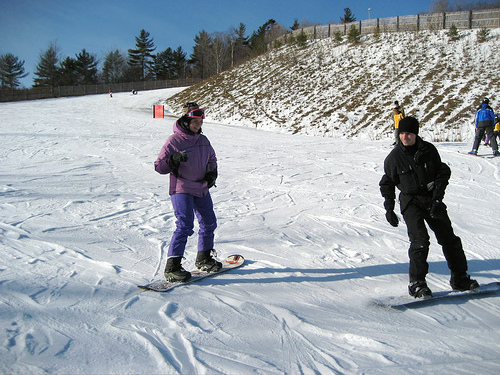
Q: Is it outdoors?
A: Yes, it is outdoors.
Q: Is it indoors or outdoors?
A: It is outdoors.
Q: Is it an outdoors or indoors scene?
A: It is outdoors.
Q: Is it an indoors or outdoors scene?
A: It is outdoors.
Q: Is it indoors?
A: No, it is outdoors.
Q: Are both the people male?
A: No, they are both male and female.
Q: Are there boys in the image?
A: No, there are no boys.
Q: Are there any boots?
A: Yes, there are boots.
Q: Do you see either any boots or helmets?
A: Yes, there are boots.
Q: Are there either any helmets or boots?
A: Yes, there are boots.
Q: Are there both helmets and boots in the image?
A: No, there are boots but no helmets.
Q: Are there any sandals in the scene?
A: No, there are no sandals.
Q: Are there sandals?
A: No, there are no sandals.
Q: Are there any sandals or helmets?
A: No, there are no sandals or helmets.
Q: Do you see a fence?
A: Yes, there is a fence.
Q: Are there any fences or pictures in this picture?
A: Yes, there is a fence.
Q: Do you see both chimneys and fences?
A: No, there is a fence but no chimneys.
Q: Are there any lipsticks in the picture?
A: No, there are no lipsticks.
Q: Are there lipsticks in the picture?
A: No, there are no lipsticks.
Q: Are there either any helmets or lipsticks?
A: No, there are no lipsticks or helmets.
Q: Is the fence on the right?
A: Yes, the fence is on the right of the image.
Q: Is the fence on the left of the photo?
A: No, the fence is on the right of the image.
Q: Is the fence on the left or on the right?
A: The fence is on the right of the image.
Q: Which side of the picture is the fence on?
A: The fence is on the right of the image.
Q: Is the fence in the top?
A: Yes, the fence is in the top of the image.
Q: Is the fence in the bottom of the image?
A: No, the fence is in the top of the image.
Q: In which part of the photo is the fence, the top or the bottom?
A: The fence is in the top of the image.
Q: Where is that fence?
A: The fence is on the hill.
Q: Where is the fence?
A: The fence is on the hill.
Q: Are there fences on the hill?
A: Yes, there is a fence on the hill.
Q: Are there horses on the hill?
A: No, there is a fence on the hill.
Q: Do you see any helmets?
A: No, there are no helmets.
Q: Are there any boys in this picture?
A: No, there are no boys.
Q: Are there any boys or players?
A: No, there are no boys or players.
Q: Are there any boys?
A: No, there are no boys.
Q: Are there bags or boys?
A: No, there are no boys or bags.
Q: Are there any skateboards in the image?
A: No, there are no skateboards.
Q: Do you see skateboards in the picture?
A: No, there are no skateboards.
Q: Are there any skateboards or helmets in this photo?
A: No, there are no skateboards or helmets.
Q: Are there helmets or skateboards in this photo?
A: No, there are no skateboards or helmets.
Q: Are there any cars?
A: No, there are no cars.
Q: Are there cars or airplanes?
A: No, there are no cars or airplanes.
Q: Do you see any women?
A: Yes, there is a woman.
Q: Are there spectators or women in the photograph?
A: Yes, there is a woman.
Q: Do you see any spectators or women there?
A: Yes, there is a woman.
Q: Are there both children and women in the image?
A: No, there is a woman but no children.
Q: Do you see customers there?
A: No, there are no customers.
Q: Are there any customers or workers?
A: No, there are no customers or workers.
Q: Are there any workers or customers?
A: No, there are no customers or workers.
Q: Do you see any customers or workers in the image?
A: No, there are no customers or workers.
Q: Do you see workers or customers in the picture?
A: No, there are no customers or workers.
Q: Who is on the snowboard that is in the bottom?
A: The woman is on the snowboard.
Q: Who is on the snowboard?
A: The woman is on the snowboard.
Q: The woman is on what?
A: The woman is on the snowboard.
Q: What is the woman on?
A: The woman is on the snowboard.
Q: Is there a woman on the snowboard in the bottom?
A: Yes, there is a woman on the snowboard.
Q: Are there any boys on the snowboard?
A: No, there is a woman on the snowboard.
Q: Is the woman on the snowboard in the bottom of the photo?
A: Yes, the woman is on the snow board.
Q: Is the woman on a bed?
A: No, the woman is on the snow board.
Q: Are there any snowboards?
A: Yes, there is a snowboard.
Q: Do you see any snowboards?
A: Yes, there is a snowboard.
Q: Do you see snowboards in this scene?
A: Yes, there is a snowboard.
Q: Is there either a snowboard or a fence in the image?
A: Yes, there is a snowboard.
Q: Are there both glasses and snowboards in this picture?
A: No, there is a snowboard but no glasses.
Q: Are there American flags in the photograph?
A: No, there are no American flags.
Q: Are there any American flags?
A: No, there are no American flags.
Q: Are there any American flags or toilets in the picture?
A: No, there are no American flags or toilets.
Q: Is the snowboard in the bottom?
A: Yes, the snowboard is in the bottom of the image.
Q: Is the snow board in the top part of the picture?
A: No, the snow board is in the bottom of the image.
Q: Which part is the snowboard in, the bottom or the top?
A: The snowboard is in the bottom of the image.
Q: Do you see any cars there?
A: No, there are no cars.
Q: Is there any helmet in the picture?
A: No, there are no helmets.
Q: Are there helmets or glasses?
A: No, there are no helmets or glasses.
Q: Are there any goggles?
A: Yes, there are goggles.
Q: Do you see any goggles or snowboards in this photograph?
A: Yes, there are goggles.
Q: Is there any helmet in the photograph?
A: No, there are no helmets.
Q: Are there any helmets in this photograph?
A: No, there are no helmets.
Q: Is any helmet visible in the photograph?
A: No, there are no helmets.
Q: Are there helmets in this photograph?
A: No, there are no helmets.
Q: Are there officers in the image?
A: No, there are no officers.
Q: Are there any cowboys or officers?
A: No, there are no officers or cowboys.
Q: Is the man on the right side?
A: Yes, the man is on the right of the image.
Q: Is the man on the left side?
A: No, the man is on the right of the image.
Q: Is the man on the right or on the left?
A: The man is on the right of the image.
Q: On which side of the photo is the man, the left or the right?
A: The man is on the right of the image.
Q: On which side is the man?
A: The man is on the right of the image.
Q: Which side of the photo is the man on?
A: The man is on the right of the image.